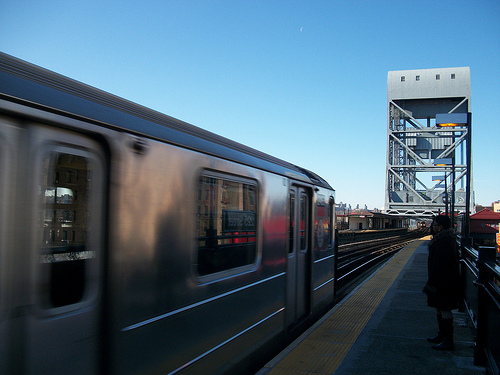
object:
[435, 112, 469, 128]
light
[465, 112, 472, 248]
post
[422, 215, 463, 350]
woman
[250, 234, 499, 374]
platform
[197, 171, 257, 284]
window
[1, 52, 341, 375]
train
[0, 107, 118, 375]
door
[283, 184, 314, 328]
door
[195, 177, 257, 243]
building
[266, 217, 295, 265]
reflection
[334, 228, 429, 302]
railroad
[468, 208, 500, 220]
roof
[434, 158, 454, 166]
light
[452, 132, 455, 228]
post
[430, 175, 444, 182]
light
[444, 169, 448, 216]
post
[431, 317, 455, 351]
boots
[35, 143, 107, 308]
window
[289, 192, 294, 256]
window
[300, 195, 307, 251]
window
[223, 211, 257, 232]
sign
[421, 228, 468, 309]
coat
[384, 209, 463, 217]
overpass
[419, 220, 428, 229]
train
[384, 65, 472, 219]
stucture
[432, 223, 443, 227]
glasses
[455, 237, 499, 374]
rail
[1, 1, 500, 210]
sky